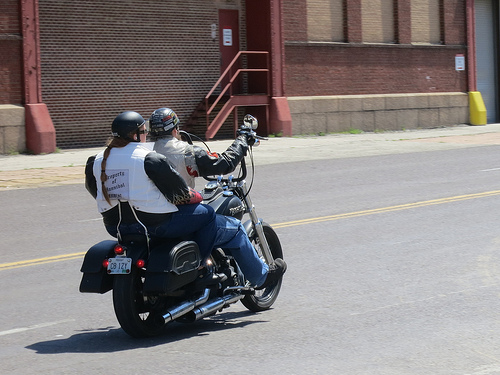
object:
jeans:
[103, 202, 218, 267]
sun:
[127, 111, 139, 118]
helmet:
[148, 107, 181, 136]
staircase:
[180, 51, 271, 141]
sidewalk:
[0, 123, 500, 190]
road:
[0, 145, 500, 375]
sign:
[222, 28, 233, 46]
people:
[84, 109, 229, 292]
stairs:
[191, 116, 217, 120]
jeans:
[213, 214, 269, 289]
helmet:
[111, 111, 146, 140]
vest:
[92, 142, 179, 214]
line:
[272, 192, 500, 229]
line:
[0, 251, 87, 267]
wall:
[37, 0, 247, 150]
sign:
[455, 54, 466, 71]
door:
[218, 8, 243, 94]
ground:
[0, 121, 500, 375]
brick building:
[0, 0, 477, 156]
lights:
[136, 260, 145, 268]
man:
[148, 105, 286, 290]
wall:
[43, 5, 225, 110]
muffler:
[153, 298, 195, 328]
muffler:
[187, 291, 246, 322]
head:
[111, 111, 148, 143]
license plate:
[107, 258, 132, 275]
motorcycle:
[77, 130, 283, 341]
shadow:
[23, 308, 273, 355]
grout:
[154, 70, 157, 72]